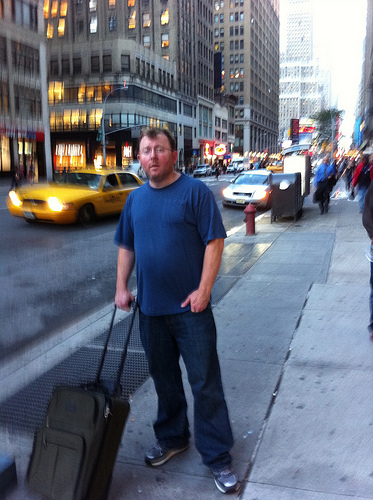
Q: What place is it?
A: It is a street.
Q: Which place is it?
A: It is a street.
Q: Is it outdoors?
A: Yes, it is outdoors.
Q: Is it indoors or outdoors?
A: It is outdoors.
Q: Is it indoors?
A: No, it is outdoors.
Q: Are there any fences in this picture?
A: No, there are no fences.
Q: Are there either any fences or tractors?
A: No, there are no fences or tractors.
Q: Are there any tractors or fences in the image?
A: No, there are no fences or tractors.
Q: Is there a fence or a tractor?
A: No, there are no fences or tractors.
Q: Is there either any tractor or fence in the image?
A: No, there are no fences or tractors.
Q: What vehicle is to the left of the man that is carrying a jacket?
A: The vehicle is a car.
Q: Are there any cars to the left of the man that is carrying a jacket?
A: Yes, there is a car to the left of the man.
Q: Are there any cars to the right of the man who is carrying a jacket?
A: No, the car is to the left of the man.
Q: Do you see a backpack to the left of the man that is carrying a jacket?
A: No, there is a car to the left of the man.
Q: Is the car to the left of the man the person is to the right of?
A: Yes, the car is to the left of the man.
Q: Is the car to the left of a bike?
A: No, the car is to the left of the man.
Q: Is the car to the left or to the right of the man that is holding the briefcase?
A: The car is to the left of the man.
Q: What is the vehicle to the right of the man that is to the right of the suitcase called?
A: The vehicle is a car.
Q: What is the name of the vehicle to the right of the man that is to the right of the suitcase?
A: The vehicle is a car.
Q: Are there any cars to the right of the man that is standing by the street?
A: Yes, there is a car to the right of the man.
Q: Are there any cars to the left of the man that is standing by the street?
A: No, the car is to the right of the man.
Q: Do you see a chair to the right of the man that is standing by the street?
A: No, there is a car to the right of the man.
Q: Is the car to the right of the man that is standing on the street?
A: Yes, the car is to the right of the man.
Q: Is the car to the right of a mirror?
A: No, the car is to the right of the man.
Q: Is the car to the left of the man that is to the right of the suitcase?
A: No, the car is to the right of the man.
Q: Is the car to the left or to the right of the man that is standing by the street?
A: The car is to the right of the man.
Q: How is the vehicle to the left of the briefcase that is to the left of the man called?
A: The vehicle is a car.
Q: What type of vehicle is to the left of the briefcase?
A: The vehicle is a car.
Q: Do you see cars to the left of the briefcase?
A: Yes, there is a car to the left of the briefcase.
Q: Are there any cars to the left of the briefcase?
A: Yes, there is a car to the left of the briefcase.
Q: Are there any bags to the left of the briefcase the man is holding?
A: No, there is a car to the left of the briefcase.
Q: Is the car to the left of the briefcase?
A: Yes, the car is to the left of the briefcase.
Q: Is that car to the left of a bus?
A: No, the car is to the left of the briefcase.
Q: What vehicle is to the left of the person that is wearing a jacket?
A: The vehicle is a car.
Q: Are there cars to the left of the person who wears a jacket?
A: Yes, there is a car to the left of the person.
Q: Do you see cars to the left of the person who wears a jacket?
A: Yes, there is a car to the left of the person.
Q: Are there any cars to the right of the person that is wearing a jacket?
A: No, the car is to the left of the person.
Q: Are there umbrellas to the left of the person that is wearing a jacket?
A: No, there is a car to the left of the person.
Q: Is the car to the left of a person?
A: Yes, the car is to the left of a person.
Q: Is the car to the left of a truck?
A: No, the car is to the left of a person.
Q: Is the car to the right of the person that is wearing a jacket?
A: No, the car is to the left of the person.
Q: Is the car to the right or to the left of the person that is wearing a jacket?
A: The car is to the left of the person.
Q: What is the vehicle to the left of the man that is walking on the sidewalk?
A: The vehicle is a car.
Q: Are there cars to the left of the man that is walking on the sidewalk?
A: Yes, there is a car to the left of the man.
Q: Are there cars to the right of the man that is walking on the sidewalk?
A: No, the car is to the left of the man.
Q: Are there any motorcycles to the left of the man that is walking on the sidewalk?
A: No, there is a car to the left of the man.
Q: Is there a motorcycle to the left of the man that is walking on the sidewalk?
A: No, there is a car to the left of the man.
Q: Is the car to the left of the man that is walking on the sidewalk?
A: Yes, the car is to the left of the man.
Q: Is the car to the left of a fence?
A: No, the car is to the left of the man.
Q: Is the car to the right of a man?
A: No, the car is to the left of a man.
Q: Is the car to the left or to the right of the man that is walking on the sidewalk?
A: The car is to the left of the man.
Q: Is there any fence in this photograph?
A: No, there are no fences.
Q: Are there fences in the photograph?
A: No, there are no fences.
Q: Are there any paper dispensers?
A: No, there are no paper dispensers.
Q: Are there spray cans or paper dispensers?
A: No, there are no paper dispensers or spray cans.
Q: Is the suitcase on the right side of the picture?
A: No, the suitcase is on the left of the image.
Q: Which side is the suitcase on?
A: The suitcase is on the left of the image.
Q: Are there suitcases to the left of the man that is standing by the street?
A: Yes, there is a suitcase to the left of the man.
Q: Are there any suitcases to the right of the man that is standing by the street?
A: No, the suitcase is to the left of the man.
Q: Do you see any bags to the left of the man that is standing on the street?
A: No, there is a suitcase to the left of the man.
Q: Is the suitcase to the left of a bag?
A: No, the suitcase is to the left of the man.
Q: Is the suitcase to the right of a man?
A: No, the suitcase is to the left of a man.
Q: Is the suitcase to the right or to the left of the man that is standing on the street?
A: The suitcase is to the left of the man.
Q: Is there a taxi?
A: Yes, there is a taxi.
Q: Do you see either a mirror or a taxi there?
A: Yes, there is a taxi.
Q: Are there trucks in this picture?
A: No, there are no trucks.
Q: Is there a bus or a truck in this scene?
A: No, there are no trucks or buses.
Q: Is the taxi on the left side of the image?
A: Yes, the taxi is on the left of the image.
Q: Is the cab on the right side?
A: No, the cab is on the left of the image.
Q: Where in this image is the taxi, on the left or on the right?
A: The taxi is on the left of the image.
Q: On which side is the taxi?
A: The taxi is on the left of the image.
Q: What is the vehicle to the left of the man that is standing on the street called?
A: The vehicle is a taxi.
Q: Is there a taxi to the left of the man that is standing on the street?
A: Yes, there is a taxi to the left of the man.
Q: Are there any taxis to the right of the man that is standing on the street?
A: No, the taxi is to the left of the man.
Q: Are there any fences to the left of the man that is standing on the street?
A: No, there is a taxi to the left of the man.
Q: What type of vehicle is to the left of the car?
A: The vehicle is a taxi.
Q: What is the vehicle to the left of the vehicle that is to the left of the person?
A: The vehicle is a taxi.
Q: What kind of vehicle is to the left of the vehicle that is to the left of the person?
A: The vehicle is a taxi.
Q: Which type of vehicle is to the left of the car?
A: The vehicle is a taxi.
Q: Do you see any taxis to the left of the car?
A: Yes, there is a taxi to the left of the car.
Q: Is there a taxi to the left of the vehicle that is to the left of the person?
A: Yes, there is a taxi to the left of the car.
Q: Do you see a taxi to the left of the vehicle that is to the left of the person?
A: Yes, there is a taxi to the left of the car.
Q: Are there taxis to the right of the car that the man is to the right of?
A: No, the taxi is to the left of the car.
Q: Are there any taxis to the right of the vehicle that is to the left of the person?
A: No, the taxi is to the left of the car.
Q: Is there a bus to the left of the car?
A: No, there is a taxi to the left of the car.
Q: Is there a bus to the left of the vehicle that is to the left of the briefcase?
A: No, there is a taxi to the left of the car.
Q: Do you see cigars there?
A: No, there are no cigars.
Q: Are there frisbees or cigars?
A: No, there are no cigars or frisbees.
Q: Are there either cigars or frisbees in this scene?
A: No, there are no cigars or frisbees.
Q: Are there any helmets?
A: No, there are no helmets.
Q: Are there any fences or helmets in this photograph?
A: No, there are no helmets or fences.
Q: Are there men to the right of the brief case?
A: Yes, there is a man to the right of the brief case.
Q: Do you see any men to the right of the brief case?
A: Yes, there is a man to the right of the brief case.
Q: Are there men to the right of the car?
A: Yes, there is a man to the right of the car.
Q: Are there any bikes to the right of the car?
A: No, there is a man to the right of the car.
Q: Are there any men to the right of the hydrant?
A: Yes, there is a man to the right of the hydrant.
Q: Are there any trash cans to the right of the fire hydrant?
A: No, there is a man to the right of the fire hydrant.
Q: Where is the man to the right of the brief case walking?
A: The man is walking on the side walk.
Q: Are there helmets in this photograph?
A: No, there are no helmets.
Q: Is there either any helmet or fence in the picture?
A: No, there are no helmets or fences.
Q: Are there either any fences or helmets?
A: No, there are no helmets or fences.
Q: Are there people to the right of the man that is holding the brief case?
A: Yes, there is a person to the right of the man.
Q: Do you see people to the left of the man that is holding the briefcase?
A: No, the person is to the right of the man.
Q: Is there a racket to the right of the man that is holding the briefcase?
A: No, there is a person to the right of the man.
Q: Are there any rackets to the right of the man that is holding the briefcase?
A: No, there is a person to the right of the man.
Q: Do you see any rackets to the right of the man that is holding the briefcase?
A: No, there is a person to the right of the man.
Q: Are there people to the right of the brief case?
A: Yes, there is a person to the right of the brief case.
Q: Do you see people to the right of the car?
A: Yes, there is a person to the right of the car.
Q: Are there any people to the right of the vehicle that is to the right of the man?
A: Yes, there is a person to the right of the car.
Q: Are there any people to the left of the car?
A: No, the person is to the right of the car.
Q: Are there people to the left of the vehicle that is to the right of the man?
A: No, the person is to the right of the car.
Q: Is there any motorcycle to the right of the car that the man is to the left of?
A: No, there is a person to the right of the car.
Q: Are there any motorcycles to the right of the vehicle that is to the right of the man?
A: No, there is a person to the right of the car.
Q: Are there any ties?
A: No, there are no ties.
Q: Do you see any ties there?
A: No, there are no ties.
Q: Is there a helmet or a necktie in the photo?
A: No, there are no ties or helmets.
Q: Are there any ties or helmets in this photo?
A: No, there are no ties or helmets.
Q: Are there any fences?
A: No, there are no fences.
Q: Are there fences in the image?
A: No, there are no fences.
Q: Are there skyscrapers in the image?
A: Yes, there are skyscrapers.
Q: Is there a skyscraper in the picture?
A: Yes, there are skyscrapers.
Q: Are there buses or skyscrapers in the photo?
A: Yes, there are skyscrapers.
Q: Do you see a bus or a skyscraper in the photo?
A: Yes, there are skyscrapers.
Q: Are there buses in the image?
A: No, there are no buses.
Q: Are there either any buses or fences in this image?
A: No, there are no buses or fences.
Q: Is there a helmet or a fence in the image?
A: No, there are no fences or helmets.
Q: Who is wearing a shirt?
A: The man is wearing a shirt.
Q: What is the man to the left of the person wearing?
A: The man is wearing a shirt.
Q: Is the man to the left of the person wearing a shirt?
A: Yes, the man is wearing a shirt.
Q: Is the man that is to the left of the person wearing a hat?
A: No, the man is wearing a shirt.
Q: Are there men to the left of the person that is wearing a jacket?
A: Yes, there is a man to the left of the person.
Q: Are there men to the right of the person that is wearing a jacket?
A: No, the man is to the left of the person.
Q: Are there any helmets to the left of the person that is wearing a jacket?
A: No, there is a man to the left of the person.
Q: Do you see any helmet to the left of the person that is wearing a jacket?
A: No, there is a man to the left of the person.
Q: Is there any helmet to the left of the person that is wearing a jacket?
A: No, there is a man to the left of the person.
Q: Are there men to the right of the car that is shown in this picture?
A: Yes, there is a man to the right of the car.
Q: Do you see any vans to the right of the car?
A: No, there is a man to the right of the car.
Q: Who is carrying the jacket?
A: The man is carrying the jacket.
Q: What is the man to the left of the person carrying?
A: The man is carrying a jacket.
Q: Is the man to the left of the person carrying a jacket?
A: Yes, the man is carrying a jacket.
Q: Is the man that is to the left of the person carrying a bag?
A: No, the man is carrying a jacket.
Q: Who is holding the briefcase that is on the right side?
A: The man is holding the brief case.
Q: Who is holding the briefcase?
A: The man is holding the brief case.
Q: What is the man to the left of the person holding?
A: The man is holding the briefcase.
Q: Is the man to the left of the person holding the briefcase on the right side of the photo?
A: Yes, the man is holding the briefcase.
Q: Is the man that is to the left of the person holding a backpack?
A: No, the man is holding the briefcase.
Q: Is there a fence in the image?
A: No, there are no fences.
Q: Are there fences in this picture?
A: No, there are no fences.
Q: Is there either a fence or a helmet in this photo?
A: No, there are no fences or helmets.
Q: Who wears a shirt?
A: The man wears a shirt.